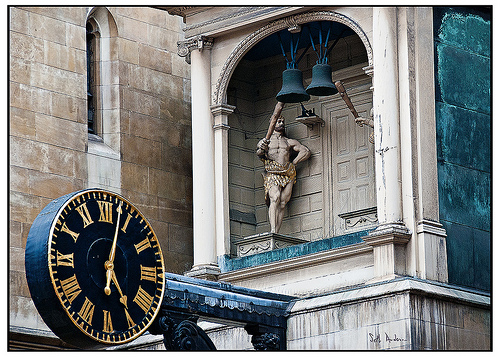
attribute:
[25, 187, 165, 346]
clock — gold, black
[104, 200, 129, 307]
hands — gold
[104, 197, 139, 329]
5:03 — time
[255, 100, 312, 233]
statue — man, shirtless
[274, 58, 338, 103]
bells — black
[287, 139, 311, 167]
arm — bent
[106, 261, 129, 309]
hour hand — brown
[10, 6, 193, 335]
wall — brown